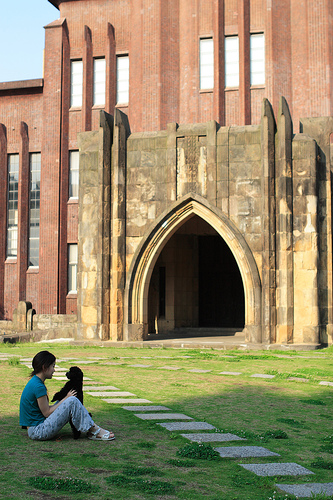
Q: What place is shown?
A: It is a yard.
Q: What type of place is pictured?
A: It is a yard.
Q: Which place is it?
A: It is a yard.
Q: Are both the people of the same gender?
A: Yes, all the people are female.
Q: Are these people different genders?
A: No, all the people are female.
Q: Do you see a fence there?
A: No, there are no fences.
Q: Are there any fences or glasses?
A: No, there are no fences or glasses.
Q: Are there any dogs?
A: Yes, there is a dog.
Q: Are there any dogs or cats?
A: Yes, there is a dog.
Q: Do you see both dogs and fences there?
A: No, there is a dog but no fences.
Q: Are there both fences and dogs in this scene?
A: No, there is a dog but no fences.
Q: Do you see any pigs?
A: No, there are no pigs.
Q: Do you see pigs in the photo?
A: No, there are no pigs.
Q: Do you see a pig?
A: No, there are no pigs.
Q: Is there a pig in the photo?
A: No, there are no pigs.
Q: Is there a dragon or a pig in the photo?
A: No, there are no pigs or dragons.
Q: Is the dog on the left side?
A: Yes, the dog is on the left of the image.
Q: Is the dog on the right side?
A: No, the dog is on the left of the image.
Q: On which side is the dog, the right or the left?
A: The dog is on the left of the image.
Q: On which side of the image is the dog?
A: The dog is on the left of the image.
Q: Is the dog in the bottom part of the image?
A: Yes, the dog is in the bottom of the image.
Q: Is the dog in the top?
A: No, the dog is in the bottom of the image.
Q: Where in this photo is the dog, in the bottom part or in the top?
A: The dog is in the bottom of the image.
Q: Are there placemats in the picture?
A: No, there are no placemats.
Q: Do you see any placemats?
A: No, there are no placemats.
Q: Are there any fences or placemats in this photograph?
A: No, there are no placemats or fences.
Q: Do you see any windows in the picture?
A: Yes, there is a window.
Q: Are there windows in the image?
A: Yes, there is a window.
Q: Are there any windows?
A: Yes, there is a window.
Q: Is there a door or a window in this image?
A: Yes, there is a window.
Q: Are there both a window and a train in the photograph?
A: No, there is a window but no trains.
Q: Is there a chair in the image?
A: No, there are no chairs.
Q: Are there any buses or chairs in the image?
A: No, there are no chairs or buses.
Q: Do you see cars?
A: No, there are no cars.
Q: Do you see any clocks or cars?
A: No, there are no cars or clocks.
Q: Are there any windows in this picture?
A: Yes, there is a window.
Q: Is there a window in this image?
A: Yes, there is a window.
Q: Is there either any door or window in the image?
A: Yes, there is a window.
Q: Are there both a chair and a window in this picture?
A: No, there is a window but no chairs.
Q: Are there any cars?
A: No, there are no cars.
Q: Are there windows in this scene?
A: Yes, there is a window.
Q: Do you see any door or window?
A: Yes, there is a window.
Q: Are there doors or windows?
A: Yes, there is a window.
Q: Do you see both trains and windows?
A: No, there is a window but no trains.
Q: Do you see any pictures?
A: No, there are no pictures.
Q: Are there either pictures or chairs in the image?
A: No, there are no pictures or chairs.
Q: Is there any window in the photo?
A: Yes, there are windows.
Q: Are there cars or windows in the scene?
A: Yes, there are windows.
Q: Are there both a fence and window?
A: No, there are windows but no fences.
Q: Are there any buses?
A: No, there are no buses.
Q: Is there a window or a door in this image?
A: Yes, there are windows.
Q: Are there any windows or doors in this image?
A: Yes, there are windows.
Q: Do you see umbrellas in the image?
A: No, there are no umbrellas.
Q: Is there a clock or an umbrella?
A: No, there are no umbrellas or clocks.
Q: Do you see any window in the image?
A: Yes, there is a window.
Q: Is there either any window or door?
A: Yes, there is a window.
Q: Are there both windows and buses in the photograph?
A: No, there is a window but no buses.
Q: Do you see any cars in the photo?
A: No, there are no cars.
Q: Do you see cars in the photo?
A: No, there are no cars.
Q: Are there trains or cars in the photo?
A: No, there are no cars or trains.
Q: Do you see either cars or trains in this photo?
A: No, there are no cars or trains.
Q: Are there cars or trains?
A: No, there are no cars or trains.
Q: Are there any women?
A: Yes, there is a woman.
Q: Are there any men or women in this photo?
A: Yes, there is a woman.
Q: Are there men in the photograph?
A: No, there are no men.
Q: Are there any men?
A: No, there are no men.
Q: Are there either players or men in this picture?
A: No, there are no men or players.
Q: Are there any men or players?
A: No, there are no men or players.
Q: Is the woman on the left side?
A: Yes, the woman is on the left of the image.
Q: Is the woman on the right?
A: No, the woman is on the left of the image.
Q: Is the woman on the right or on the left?
A: The woman is on the left of the image.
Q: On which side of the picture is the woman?
A: The woman is on the left of the image.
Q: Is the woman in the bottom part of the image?
A: Yes, the woman is in the bottom of the image.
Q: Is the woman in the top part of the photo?
A: No, the woman is in the bottom of the image.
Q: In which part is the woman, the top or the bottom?
A: The woman is in the bottom of the image.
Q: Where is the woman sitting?
A: The woman is sitting in the grass.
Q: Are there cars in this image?
A: No, there are no cars.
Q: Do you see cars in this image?
A: No, there are no cars.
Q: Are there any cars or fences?
A: No, there are no cars or fences.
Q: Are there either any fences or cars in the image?
A: No, there are no cars or fences.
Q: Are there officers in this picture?
A: No, there are no officers.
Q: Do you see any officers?
A: No, there are no officers.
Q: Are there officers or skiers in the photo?
A: No, there are no officers or skiers.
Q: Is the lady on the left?
A: Yes, the lady is on the left of the image.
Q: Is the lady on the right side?
A: No, the lady is on the left of the image.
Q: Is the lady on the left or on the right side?
A: The lady is on the left of the image.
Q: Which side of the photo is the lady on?
A: The lady is on the left of the image.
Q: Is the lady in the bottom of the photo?
A: Yes, the lady is in the bottom of the image.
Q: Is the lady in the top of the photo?
A: No, the lady is in the bottom of the image.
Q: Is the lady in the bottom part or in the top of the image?
A: The lady is in the bottom of the image.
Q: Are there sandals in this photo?
A: Yes, there are sandals.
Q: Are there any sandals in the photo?
A: Yes, there are sandals.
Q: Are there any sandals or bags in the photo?
A: Yes, there are sandals.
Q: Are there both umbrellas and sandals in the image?
A: No, there are sandals but no umbrellas.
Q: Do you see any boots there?
A: No, there are no boots.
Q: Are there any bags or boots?
A: No, there are no boots or bags.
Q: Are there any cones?
A: No, there are no cones.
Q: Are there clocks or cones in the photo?
A: No, there are no cones or clocks.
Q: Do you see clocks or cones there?
A: No, there are no cones or clocks.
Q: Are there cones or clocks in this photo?
A: No, there are no cones or clocks.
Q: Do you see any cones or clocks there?
A: No, there are no cones or clocks.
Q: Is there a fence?
A: No, there are no fences.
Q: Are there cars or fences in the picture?
A: No, there are no fences or cars.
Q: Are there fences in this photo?
A: No, there are no fences.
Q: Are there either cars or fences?
A: No, there are no fences or cars.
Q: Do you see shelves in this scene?
A: No, there are no shelves.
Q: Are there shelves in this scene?
A: No, there are no shelves.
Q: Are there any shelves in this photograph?
A: No, there are no shelves.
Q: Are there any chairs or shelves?
A: No, there are no shelves or chairs.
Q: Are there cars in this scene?
A: No, there are no cars.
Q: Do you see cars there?
A: No, there are no cars.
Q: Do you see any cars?
A: No, there are no cars.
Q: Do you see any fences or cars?
A: No, there are no cars or fences.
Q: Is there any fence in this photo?
A: No, there are no fences.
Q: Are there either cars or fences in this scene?
A: No, there are no fences or cars.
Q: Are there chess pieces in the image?
A: No, there are no chess pieces.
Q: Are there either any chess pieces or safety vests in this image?
A: No, there are no chess pieces or safety vests.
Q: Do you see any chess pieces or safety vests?
A: No, there are no chess pieces or safety vests.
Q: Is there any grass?
A: Yes, there is grass.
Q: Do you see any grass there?
A: Yes, there is grass.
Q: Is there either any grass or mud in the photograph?
A: Yes, there is grass.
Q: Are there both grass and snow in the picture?
A: No, there is grass but no snow.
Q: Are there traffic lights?
A: No, there are no traffic lights.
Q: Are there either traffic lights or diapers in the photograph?
A: No, there are no traffic lights or diapers.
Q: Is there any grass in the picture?
A: Yes, there is grass.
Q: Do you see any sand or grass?
A: Yes, there is grass.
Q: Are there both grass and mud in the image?
A: No, there is grass but no mud.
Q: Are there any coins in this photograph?
A: No, there are no coins.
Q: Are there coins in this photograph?
A: No, there are no coins.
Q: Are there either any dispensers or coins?
A: No, there are no coins or dispensers.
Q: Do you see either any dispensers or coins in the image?
A: No, there are no coins or dispensers.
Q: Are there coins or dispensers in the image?
A: No, there are no coins or dispensers.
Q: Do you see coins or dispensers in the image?
A: No, there are no coins or dispensers.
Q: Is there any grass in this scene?
A: Yes, there is grass.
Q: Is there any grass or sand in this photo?
A: Yes, there is grass.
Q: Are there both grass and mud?
A: No, there is grass but no mud.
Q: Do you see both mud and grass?
A: No, there is grass but no mud.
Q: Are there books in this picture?
A: No, there are no books.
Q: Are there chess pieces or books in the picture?
A: No, there are no books or chess pieces.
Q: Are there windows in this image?
A: Yes, there are windows.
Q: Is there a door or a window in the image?
A: Yes, there are windows.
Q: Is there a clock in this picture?
A: No, there are no clocks.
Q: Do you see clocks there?
A: No, there are no clocks.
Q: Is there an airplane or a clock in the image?
A: No, there are no clocks or airplanes.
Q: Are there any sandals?
A: Yes, there are sandals.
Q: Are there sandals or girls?
A: Yes, there are sandals.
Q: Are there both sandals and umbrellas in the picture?
A: No, there are sandals but no umbrellas.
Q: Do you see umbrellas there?
A: No, there are no umbrellas.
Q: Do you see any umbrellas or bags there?
A: No, there are no umbrellas or bags.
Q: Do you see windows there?
A: Yes, there is a window.